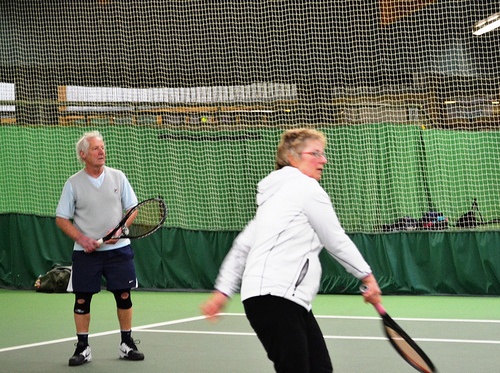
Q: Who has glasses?
A: The woman.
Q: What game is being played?
A: Tennis.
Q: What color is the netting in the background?
A: Green.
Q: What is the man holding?
A: Tennis racket.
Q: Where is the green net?
A: Surrounding the court.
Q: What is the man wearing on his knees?
A: Braces.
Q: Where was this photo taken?
A: At a tennis court.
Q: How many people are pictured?
A: Two.